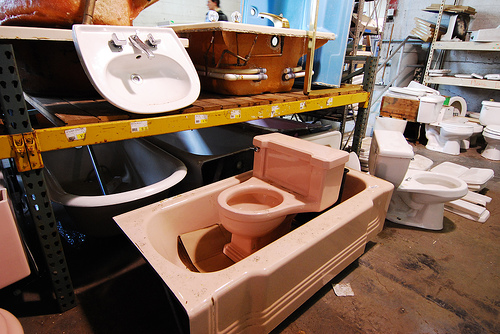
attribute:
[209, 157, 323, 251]
sink — pink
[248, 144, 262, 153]
handle — silver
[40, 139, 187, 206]
bathtub — white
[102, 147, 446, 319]
tub — pink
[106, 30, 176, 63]
faucet — brass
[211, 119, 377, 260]
toilet — pink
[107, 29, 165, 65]
faucet — metal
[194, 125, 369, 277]
toilet — pink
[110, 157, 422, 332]
bathtub — pink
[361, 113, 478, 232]
toilet — white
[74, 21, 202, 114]
sink — white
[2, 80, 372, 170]
shelf — yellow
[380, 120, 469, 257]
toilet — white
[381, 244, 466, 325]
floor — brown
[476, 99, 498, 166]
toilet — pink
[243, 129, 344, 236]
toilet — tan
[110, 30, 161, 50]
handles — silver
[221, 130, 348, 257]
toilet — not in use